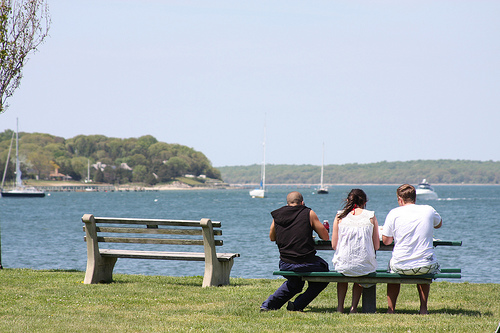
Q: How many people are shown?
A: 3.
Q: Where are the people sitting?
A: A table.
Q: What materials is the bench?
A: Wood and concrete.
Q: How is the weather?
A: Clear.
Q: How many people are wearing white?
A: 2.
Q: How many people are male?
A: 2.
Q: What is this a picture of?
A: A body of water, with boats on it, surrounded by greenery, benches and people.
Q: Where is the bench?
A: In front of the body of water.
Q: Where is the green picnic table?
A: To the right of the bench.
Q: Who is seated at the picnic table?
A: Three people.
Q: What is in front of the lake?
A: Benches.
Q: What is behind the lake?
A: Bushes.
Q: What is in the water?
A: A boat.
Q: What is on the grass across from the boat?
A: An empty bench.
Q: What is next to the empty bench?
A: A picnic table.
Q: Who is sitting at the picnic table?
A: Three people.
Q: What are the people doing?
A: Eating.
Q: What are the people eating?
A: Picnic food.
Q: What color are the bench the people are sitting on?
A: Green.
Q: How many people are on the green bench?
A: 3.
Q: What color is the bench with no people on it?
A: Grey.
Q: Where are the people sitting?
A: On a bench.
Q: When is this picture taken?
A: In the daytime.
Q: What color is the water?
A: Blue.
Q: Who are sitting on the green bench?
A: 3 people.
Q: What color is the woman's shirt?
A: White.